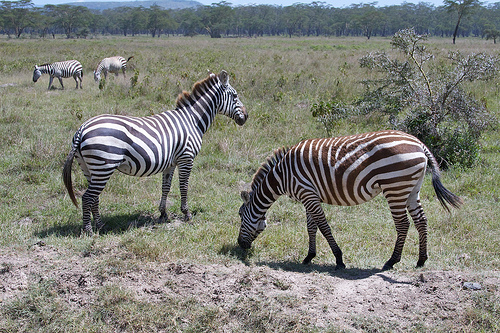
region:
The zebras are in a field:
[10, 16, 465, 316]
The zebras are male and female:
[0, 40, 496, 318]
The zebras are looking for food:
[13, 15, 478, 295]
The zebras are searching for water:
[30, 35, 477, 288]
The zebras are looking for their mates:
[15, 45, 457, 331]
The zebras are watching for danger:
[21, 55, 487, 330]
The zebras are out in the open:
[20, 40, 472, 330]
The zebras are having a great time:
[30, 30, 470, 285]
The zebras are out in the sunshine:
[25, 27, 478, 325]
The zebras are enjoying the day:
[26, 35, 476, 299]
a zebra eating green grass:
[235, 127, 460, 270]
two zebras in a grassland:
[31, 54, 136, 90]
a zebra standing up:
[60, 70, 249, 240]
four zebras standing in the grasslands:
[30, 54, 462, 274]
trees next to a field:
[2, 0, 494, 43]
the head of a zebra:
[176, 69, 248, 126]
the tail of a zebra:
[421, 145, 461, 212]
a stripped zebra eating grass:
[237, 130, 464, 272]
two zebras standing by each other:
[63, 67, 463, 274]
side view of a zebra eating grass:
[234, 129, 460, 277]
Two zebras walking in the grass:
[31, 54, 126, 89]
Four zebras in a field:
[29, 52, 463, 274]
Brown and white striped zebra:
[237, 129, 462, 274]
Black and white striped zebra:
[60, 67, 249, 234]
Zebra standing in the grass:
[58, 69, 251, 237]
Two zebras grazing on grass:
[28, 53, 135, 90]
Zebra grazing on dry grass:
[236, 128, 462, 271]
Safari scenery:
[0, 1, 497, 329]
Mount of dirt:
[0, 241, 497, 331]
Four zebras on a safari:
[30, 55, 464, 273]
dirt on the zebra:
[293, 130, 424, 208]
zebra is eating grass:
[231, 177, 276, 254]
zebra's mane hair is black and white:
[238, 145, 290, 198]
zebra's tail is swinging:
[427, 159, 463, 210]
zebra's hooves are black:
[295, 239, 430, 275]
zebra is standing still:
[43, 67, 249, 229]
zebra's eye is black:
[224, 93, 241, 104]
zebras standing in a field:
[0, 2, 498, 332]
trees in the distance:
[1, 2, 492, 43]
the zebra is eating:
[25, 59, 87, 95]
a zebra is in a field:
[231, 128, 458, 269]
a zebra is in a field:
[61, 70, 246, 240]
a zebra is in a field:
[27, 59, 86, 92]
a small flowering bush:
[314, 23, 497, 175]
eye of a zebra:
[230, 93, 237, 99]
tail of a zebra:
[60, 126, 86, 206]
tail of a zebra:
[420, 142, 456, 212]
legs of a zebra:
[295, 191, 342, 266]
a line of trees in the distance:
[0, 2, 497, 34]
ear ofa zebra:
[241, 190, 248, 202]